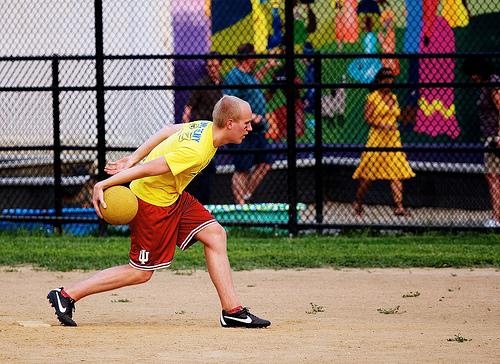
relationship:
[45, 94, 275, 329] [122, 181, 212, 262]
boy wearing shorts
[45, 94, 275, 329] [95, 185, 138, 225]
boy throwing kickball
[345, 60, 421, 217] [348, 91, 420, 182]
woman wearing dress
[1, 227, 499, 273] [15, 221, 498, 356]
green grass along field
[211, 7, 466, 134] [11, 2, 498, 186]
painting on wall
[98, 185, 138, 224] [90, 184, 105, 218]
kickball in hand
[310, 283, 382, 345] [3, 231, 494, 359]
dirt in field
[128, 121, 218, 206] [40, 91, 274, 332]
t-shirt on boy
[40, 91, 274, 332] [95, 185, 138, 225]
boy pitching kickball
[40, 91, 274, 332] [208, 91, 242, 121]
boy has hair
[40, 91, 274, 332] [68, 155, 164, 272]
boy has kickball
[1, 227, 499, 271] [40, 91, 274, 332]
green grass behind boy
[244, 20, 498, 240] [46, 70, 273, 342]
fence behind boy